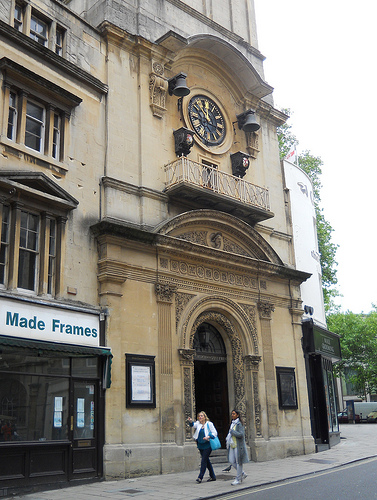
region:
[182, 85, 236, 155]
clock on front of building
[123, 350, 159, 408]
marquee on front of building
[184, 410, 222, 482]
woman walking on sidewalk pointing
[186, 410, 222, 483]
woman carrying blue pocketbook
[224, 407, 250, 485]
woman wearing long gray coat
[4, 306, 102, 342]
advertisement on store front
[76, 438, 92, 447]
mail slot on store door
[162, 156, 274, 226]
balcony beneath clock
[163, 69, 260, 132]
two bells on either side of clock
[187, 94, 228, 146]
A black clock with gold on it.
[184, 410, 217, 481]
A blonde woman walking in jeans holding flowers.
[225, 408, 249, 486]
A dark haired woman in grey walking.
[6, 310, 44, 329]
The word Made.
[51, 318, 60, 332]
Blue F in Frames.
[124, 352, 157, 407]
A large black frame with white paper inside that has writing on it.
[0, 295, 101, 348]
A long white sign that says Made Frames.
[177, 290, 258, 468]
A large concrete archway on a building.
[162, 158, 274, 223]
A brown balcony under a clock.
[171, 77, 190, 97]
Black bell to the left of a clock.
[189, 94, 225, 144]
clock on the wall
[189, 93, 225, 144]
clock face is black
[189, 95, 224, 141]
numbers and hands are gold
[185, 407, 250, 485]
people on side walk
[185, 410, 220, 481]
a woman is walking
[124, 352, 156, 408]
sign on the building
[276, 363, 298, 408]
the sign is black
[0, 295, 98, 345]
sign is white and blue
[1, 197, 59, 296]
windows on the wall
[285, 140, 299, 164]
flag on the roof